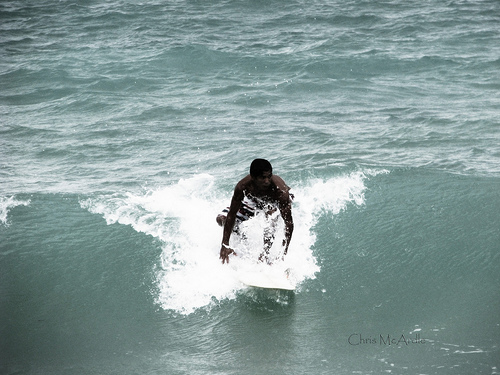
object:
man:
[217, 157, 296, 263]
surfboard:
[228, 243, 291, 290]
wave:
[0, 169, 494, 298]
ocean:
[1, 1, 499, 374]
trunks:
[222, 194, 294, 234]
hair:
[251, 159, 269, 173]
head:
[251, 159, 273, 190]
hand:
[217, 247, 238, 264]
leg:
[219, 200, 257, 246]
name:
[349, 334, 428, 347]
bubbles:
[275, 288, 326, 306]